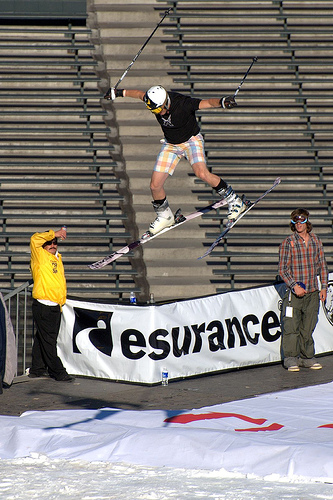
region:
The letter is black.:
[260, 307, 281, 345]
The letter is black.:
[240, 310, 260, 346]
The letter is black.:
[223, 316, 247, 350]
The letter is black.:
[204, 315, 226, 357]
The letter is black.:
[190, 317, 206, 359]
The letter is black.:
[170, 322, 191, 358]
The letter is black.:
[147, 324, 171, 363]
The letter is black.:
[117, 323, 147, 363]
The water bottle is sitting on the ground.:
[156, 360, 175, 392]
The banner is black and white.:
[20, 265, 332, 394]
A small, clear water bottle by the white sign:
[159, 367, 172, 389]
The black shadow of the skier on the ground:
[20, 385, 189, 433]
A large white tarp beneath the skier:
[15, 403, 332, 474]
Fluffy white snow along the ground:
[10, 454, 328, 498]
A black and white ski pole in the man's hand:
[229, 55, 263, 110]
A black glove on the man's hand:
[218, 95, 238, 113]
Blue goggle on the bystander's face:
[288, 215, 310, 227]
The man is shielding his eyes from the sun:
[29, 222, 75, 258]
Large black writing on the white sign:
[102, 307, 288, 365]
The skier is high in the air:
[82, 37, 300, 271]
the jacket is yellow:
[22, 228, 74, 298]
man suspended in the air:
[91, 74, 264, 282]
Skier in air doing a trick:
[68, 0, 292, 276]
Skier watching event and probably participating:
[273, 194, 325, 374]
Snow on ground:
[2, 451, 328, 497]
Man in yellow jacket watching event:
[23, 212, 77, 390]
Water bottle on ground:
[159, 363, 173, 395]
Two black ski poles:
[71, 0, 280, 122]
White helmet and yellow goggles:
[140, 80, 176, 120]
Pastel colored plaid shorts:
[142, 131, 220, 181]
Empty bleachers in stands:
[4, 4, 331, 302]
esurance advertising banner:
[32, 269, 330, 402]